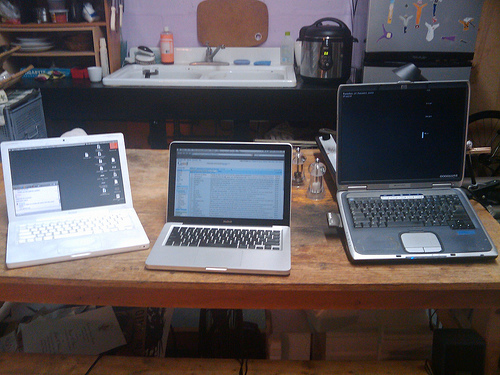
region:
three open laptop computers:
[16, 134, 458, 258]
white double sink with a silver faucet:
[122, 42, 289, 84]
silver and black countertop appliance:
[304, 21, 351, 78]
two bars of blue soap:
[236, 58, 267, 65]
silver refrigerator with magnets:
[372, 3, 472, 43]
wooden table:
[6, 272, 493, 303]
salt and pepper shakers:
[295, 146, 327, 193]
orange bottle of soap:
[161, 26, 173, 63]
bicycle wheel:
[473, 115, 495, 142]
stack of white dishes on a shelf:
[20, 36, 50, 51]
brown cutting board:
[192, 0, 264, 45]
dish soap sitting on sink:
[157, 24, 177, 68]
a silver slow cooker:
[296, 19, 358, 88]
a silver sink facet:
[190, 42, 227, 67]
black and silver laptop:
[330, 79, 498, 265]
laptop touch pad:
[390, 225, 450, 255]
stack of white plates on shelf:
[6, 31, 52, 49]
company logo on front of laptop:
[216, 215, 236, 225]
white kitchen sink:
[111, 22, 291, 87]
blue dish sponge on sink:
[248, 58, 273, 65]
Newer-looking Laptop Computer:
[156, 137, 291, 272]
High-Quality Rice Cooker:
[290, 10, 361, 85]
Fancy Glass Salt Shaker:
[305, 155, 325, 200]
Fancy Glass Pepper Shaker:
[285, 140, 305, 185]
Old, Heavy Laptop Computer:
[330, 80, 495, 260]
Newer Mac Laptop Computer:
[0, 120, 150, 265]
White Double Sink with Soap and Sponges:
[100, 40, 295, 90]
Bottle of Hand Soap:
[155, 21, 180, 64]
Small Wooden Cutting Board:
[190, 0, 265, 50]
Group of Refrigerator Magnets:
[373, 0, 481, 50]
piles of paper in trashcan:
[0, 301, 159, 358]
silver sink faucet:
[198, 43, 229, 68]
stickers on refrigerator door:
[375, 0, 477, 55]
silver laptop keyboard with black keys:
[150, 222, 296, 283]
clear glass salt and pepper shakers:
[292, 150, 325, 205]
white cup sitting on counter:
[85, 64, 102, 86]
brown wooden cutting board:
[190, 3, 269, 46]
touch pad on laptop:
[397, 229, 447, 255]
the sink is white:
[126, 25, 310, 107]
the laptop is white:
[1, 129, 146, 286]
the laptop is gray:
[152, 122, 316, 309]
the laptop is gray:
[330, 65, 491, 282]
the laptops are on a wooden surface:
[1, 75, 496, 310]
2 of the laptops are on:
[1, 130, 291, 230]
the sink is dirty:
[135, 40, 296, 101]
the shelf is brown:
[3, 0, 117, 88]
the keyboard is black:
[175, 221, 282, 248]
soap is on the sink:
[232, 49, 274, 73]